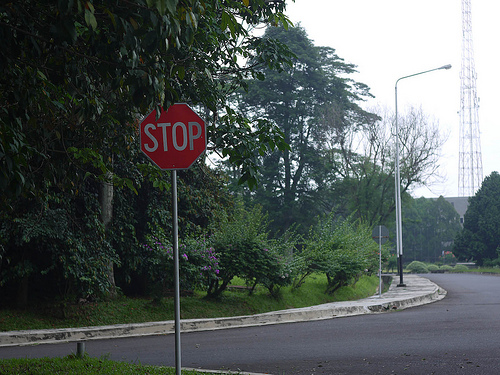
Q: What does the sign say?
A: STOP.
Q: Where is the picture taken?
A: On the side of a road.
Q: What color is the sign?
A: Red.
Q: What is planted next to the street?
A: Bushes.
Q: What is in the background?
A: A tower.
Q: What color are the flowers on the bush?
A: Pink.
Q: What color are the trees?
A: Green.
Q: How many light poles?
A: One.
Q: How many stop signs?
A: One.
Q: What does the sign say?
A: Stop.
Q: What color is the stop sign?
A: Red.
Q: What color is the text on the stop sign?
A: White.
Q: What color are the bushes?
A: Green.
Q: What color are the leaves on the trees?
A: Green.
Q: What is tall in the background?
A: Radio tower.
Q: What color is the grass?
A: Green.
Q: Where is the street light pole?
A: On the side of the road.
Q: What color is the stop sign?
A: Red and white.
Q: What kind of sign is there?
A: STOP.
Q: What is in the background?
A: A tower.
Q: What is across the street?
A: Trees and bushes.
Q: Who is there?
A: No one.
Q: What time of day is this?
A: Daytime.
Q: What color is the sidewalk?
A: White.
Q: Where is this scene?
A: On a roadway.